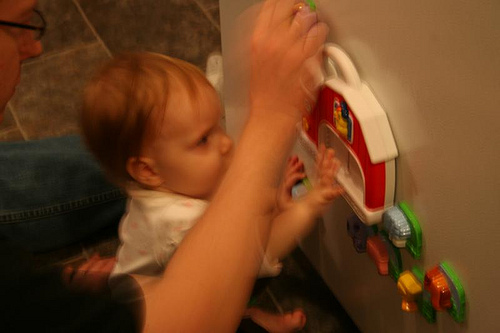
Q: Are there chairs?
A: No, there are no chairs.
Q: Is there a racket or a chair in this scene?
A: No, there are no chairs or rackets.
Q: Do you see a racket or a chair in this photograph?
A: No, there are no chairs or rackets.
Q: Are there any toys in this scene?
A: Yes, there is a toy.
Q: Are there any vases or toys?
A: Yes, there is a toy.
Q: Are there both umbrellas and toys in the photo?
A: No, there is a toy but no umbrellas.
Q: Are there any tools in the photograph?
A: No, there are no tools.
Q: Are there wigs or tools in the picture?
A: No, there are no tools or wigs.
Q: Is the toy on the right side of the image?
A: Yes, the toy is on the right of the image.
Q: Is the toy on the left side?
A: No, the toy is on the right of the image.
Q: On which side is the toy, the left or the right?
A: The toy is on the right of the image.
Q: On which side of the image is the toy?
A: The toy is on the right of the image.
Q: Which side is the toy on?
A: The toy is on the right of the image.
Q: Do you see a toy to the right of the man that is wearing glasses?
A: Yes, there is a toy to the right of the man.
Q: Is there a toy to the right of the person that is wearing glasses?
A: Yes, there is a toy to the right of the man.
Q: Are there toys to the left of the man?
A: No, the toy is to the right of the man.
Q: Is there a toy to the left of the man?
A: No, the toy is to the right of the man.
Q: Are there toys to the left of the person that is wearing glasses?
A: No, the toy is to the right of the man.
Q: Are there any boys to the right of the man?
A: No, there is a toy to the right of the man.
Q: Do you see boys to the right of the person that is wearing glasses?
A: No, there is a toy to the right of the man.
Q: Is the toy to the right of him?
A: Yes, the toy is to the right of a man.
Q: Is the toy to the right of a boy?
A: No, the toy is to the right of a man.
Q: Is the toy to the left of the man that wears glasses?
A: No, the toy is to the right of the man.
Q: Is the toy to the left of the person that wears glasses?
A: No, the toy is to the right of the man.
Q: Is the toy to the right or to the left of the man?
A: The toy is to the right of the man.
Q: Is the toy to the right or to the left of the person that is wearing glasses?
A: The toy is to the right of the man.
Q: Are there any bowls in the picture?
A: No, there are no bowls.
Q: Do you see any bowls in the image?
A: No, there are no bowls.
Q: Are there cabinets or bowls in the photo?
A: No, there are no bowls or cabinets.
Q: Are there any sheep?
A: No, there are no sheep.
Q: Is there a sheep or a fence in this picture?
A: No, there are no sheep or fences.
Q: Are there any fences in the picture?
A: No, there are no fences.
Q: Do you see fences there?
A: No, there are no fences.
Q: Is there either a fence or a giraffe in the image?
A: No, there are no fences or giraffes.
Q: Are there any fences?
A: No, there are no fences.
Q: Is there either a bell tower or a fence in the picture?
A: No, there are no fences or bell towers.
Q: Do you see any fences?
A: No, there are no fences.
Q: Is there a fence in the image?
A: No, there are no fences.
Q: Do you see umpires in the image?
A: No, there are no umpires.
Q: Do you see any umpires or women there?
A: No, there are no umpires or women.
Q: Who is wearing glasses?
A: The man is wearing glasses.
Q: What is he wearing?
A: The man is wearing glasses.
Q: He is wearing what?
A: The man is wearing glasses.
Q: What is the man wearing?
A: The man is wearing glasses.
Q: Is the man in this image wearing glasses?
A: Yes, the man is wearing glasses.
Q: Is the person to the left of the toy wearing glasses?
A: Yes, the man is wearing glasses.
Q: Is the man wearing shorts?
A: No, the man is wearing glasses.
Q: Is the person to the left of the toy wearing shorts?
A: No, the man is wearing glasses.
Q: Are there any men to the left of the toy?
A: Yes, there is a man to the left of the toy.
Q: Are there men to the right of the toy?
A: No, the man is to the left of the toy.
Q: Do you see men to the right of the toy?
A: No, the man is to the left of the toy.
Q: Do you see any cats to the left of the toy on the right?
A: No, there is a man to the left of the toy.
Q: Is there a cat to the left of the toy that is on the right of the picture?
A: No, there is a man to the left of the toy.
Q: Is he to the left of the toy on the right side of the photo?
A: Yes, the man is to the left of the toy.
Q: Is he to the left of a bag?
A: No, the man is to the left of the toy.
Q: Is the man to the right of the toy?
A: No, the man is to the left of the toy.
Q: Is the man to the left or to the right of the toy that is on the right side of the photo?
A: The man is to the left of the toy.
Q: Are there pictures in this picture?
A: No, there are no pictures.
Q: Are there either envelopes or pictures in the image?
A: No, there are no pictures or envelopes.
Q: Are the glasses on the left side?
A: Yes, the glasses are on the left of the image.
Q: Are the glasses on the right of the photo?
A: No, the glasses are on the left of the image.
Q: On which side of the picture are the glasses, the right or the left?
A: The glasses are on the left of the image.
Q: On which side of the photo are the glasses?
A: The glasses are on the left of the image.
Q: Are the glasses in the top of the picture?
A: Yes, the glasses are in the top of the image.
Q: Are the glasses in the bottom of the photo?
A: No, the glasses are in the top of the image.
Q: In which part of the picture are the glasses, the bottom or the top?
A: The glasses are in the top of the image.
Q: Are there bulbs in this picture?
A: No, there are no bulbs.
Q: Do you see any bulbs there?
A: No, there are no bulbs.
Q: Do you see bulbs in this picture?
A: No, there are no bulbs.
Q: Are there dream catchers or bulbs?
A: No, there are no bulbs or dream catchers.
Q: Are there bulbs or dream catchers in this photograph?
A: No, there are no bulbs or dream catchers.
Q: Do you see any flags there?
A: No, there are no flags.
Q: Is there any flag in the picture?
A: No, there are no flags.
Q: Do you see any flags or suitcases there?
A: No, there are no flags or suitcases.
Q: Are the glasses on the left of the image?
A: Yes, the glasses are on the left of the image.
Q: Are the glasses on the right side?
A: No, the glasses are on the left of the image.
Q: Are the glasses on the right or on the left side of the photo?
A: The glasses are on the left of the image.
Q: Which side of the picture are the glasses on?
A: The glasses are on the left of the image.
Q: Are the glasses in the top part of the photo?
A: Yes, the glasses are in the top of the image.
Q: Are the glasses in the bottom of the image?
A: No, the glasses are in the top of the image.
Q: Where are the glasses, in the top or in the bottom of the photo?
A: The glasses are in the top of the image.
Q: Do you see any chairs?
A: No, there are no chairs.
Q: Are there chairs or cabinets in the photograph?
A: No, there are no chairs or cabinets.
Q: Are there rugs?
A: No, there are no rugs.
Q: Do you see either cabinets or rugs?
A: No, there are no rugs or cabinets.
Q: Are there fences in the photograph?
A: No, there are no fences.